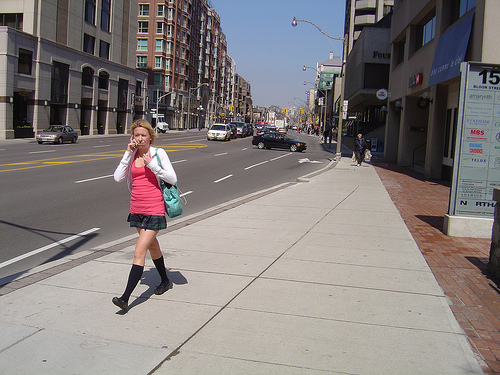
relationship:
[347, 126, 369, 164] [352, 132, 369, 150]
person wearing jacket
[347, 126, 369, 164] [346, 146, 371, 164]
person carrying bags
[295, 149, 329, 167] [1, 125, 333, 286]
traffic arrows are painted on road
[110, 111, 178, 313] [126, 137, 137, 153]
woman talking on cellphone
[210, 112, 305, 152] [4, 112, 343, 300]
vehicles are on road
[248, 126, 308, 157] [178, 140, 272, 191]
car on street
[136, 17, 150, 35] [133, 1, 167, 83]
window on side of a building